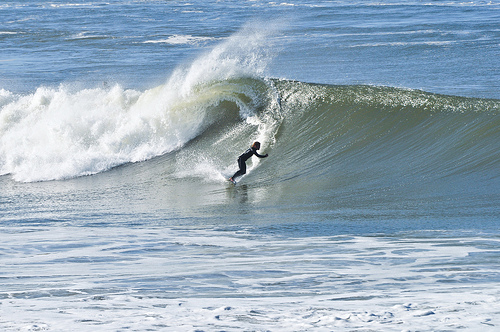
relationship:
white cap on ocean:
[2, 62, 276, 194] [2, 2, 499, 329]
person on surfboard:
[225, 137, 271, 185] [212, 146, 267, 190]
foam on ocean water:
[1, 55, 248, 185] [0, 0, 499, 331]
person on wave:
[229, 142, 268, 184] [0, 81, 497, 191]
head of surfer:
[251, 142, 260, 150] [241, 138, 261, 163]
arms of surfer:
[253, 143, 275, 170] [217, 131, 282, 206]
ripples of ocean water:
[122, 278, 403, 329] [0, 0, 499, 331]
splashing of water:
[44, 12, 225, 151] [21, 22, 153, 152]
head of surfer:
[242, 132, 271, 158] [236, 134, 268, 192]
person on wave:
[229, 142, 268, 184] [167, 71, 498, 178]